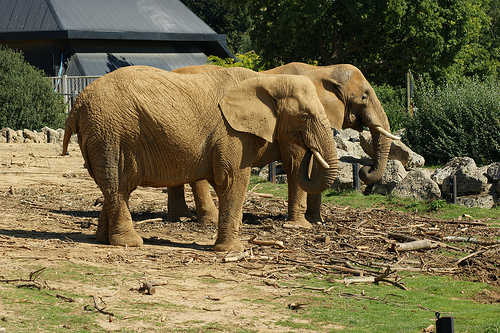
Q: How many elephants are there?
A: Two.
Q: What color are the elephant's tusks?
A: White.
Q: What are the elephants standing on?
A: Branches.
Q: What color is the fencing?
A: White.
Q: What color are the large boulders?
A: Grey.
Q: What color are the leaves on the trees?
A: Green.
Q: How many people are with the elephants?
A: Zero.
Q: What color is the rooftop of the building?
A: Blue-grey.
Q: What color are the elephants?
A: Brown.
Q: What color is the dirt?
A: Brown.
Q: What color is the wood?
A: Brown.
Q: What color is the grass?
A: Green.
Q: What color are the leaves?
A: Green.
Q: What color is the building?
A: Gray.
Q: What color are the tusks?
A: White.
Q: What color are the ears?
A: Brown.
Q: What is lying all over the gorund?
A: Twigs of wood.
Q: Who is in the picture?
A: Elephants.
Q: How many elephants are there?
A: Two.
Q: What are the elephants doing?
A: Standing.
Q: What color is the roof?
A: Gray.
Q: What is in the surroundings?
A: Green trees.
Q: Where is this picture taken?
A: In a zoo.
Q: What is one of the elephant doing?
A: Eating.